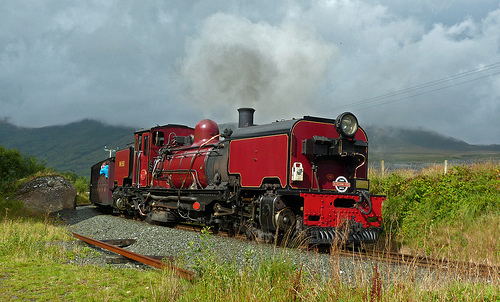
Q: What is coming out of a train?
A: Black smoke.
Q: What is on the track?
A: A train.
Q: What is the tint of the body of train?
A: Red.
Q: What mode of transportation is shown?
A: Train.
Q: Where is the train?
A: On the tracks.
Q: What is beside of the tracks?
A: Gravel.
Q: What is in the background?
A: Mountains.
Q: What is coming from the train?
A: Smoke.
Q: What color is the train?
A: Red.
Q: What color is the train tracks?
A: Red.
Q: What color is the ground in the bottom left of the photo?
A: Green.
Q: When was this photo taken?
A: Daytime.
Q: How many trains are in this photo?
A: One.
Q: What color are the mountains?
A: Dark Grey.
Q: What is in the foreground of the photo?
A: Grass.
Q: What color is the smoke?
A: White and Grey.